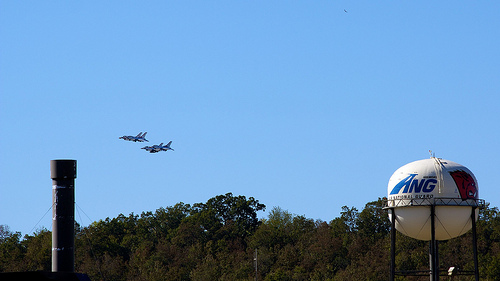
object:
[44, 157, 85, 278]
tower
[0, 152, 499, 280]
town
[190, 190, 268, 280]
tree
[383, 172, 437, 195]
letter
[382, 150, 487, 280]
water tower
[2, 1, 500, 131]
sky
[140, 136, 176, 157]
plane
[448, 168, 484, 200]
logo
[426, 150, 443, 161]
point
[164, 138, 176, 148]
tail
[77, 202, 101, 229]
string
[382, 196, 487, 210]
railing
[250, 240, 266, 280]
pole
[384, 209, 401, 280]
support pole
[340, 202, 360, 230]
branch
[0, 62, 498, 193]
background